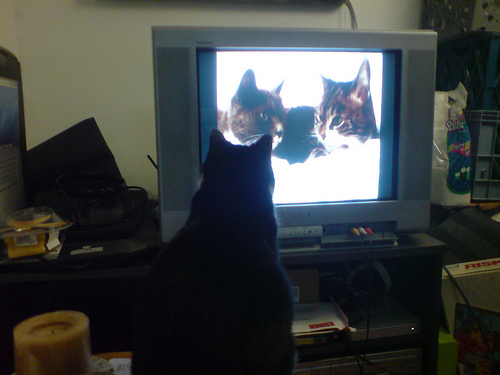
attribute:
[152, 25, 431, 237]
tv — on, large, gray, silver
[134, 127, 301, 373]
cat — sitting, black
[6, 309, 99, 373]
candle — yellow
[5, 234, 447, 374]
stand — black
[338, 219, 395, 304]
cords — yellow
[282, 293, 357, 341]
papers — white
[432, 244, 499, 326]
box — risk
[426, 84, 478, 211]
bag — plastic, white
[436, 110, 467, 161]
toilet paper — quilted northern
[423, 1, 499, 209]
crates — stacked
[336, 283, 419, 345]
dvd player — silver